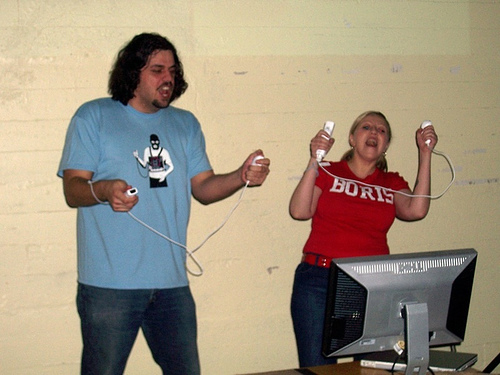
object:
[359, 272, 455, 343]
back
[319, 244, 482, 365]
monitor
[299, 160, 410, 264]
shirt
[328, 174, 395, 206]
boris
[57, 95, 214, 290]
shirt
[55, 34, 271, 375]
man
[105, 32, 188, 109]
hair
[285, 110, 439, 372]
woman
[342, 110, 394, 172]
hair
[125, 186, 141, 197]
controller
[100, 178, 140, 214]
hands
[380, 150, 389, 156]
earring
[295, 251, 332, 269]
belt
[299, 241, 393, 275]
waist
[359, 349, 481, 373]
laptop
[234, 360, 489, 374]
desk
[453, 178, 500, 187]
crack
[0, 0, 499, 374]
wall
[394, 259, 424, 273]
words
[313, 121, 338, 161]
remote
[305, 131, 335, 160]
hand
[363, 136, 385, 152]
grin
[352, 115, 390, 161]
face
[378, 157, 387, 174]
streaks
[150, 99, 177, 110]
beard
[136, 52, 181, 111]
face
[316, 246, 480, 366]
television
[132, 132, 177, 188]
picture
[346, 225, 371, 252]
red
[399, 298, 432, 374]
stand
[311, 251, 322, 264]
loop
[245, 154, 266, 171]
nunchuck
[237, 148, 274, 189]
hand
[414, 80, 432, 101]
paint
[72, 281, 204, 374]
jeans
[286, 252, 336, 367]
jeans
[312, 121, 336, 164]
controller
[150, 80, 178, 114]
hair